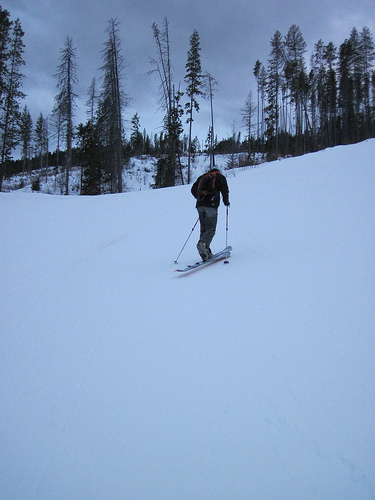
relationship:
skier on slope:
[174, 158, 238, 268] [2, 137, 374, 499]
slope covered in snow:
[2, 137, 374, 499] [272, 163, 372, 247]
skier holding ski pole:
[174, 158, 238, 268] [225, 204, 230, 262]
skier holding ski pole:
[174, 158, 238, 268] [172, 220, 202, 260]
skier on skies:
[174, 158, 238, 268] [178, 243, 237, 277]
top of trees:
[257, 28, 304, 53] [239, 22, 375, 163]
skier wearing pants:
[174, 158, 238, 268] [193, 206, 222, 259]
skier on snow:
[174, 158, 238, 268] [272, 163, 372, 247]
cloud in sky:
[33, 88, 147, 134] [1, 2, 373, 168]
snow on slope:
[272, 163, 372, 247] [2, 137, 374, 499]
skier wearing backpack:
[174, 158, 238, 268] [193, 172, 220, 201]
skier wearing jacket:
[174, 158, 238, 268] [191, 174, 230, 210]